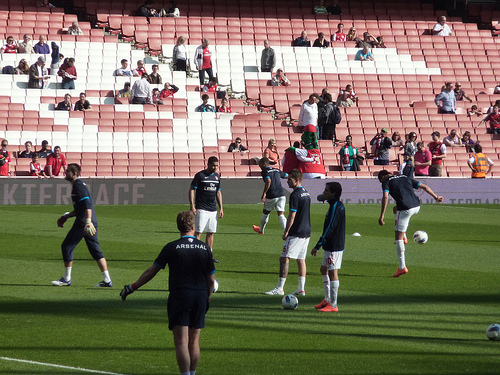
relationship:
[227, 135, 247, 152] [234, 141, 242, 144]
man wearing black sunglasses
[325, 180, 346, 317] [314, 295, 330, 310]
man wearing shoe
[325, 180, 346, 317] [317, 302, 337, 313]
man wearing shoe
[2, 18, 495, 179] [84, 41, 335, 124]
people on bunch seats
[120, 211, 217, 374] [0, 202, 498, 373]
man around field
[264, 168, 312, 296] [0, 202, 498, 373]
man around field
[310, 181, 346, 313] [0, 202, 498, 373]
man around field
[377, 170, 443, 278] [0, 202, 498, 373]
man around field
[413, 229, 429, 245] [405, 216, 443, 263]
ball in air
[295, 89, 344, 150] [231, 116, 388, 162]
people on stands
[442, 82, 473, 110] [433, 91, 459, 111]
person holds mascot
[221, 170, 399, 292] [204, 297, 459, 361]
people on astroturf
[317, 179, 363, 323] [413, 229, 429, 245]
man kick ball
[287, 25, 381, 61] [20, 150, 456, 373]
crowd watch soccer game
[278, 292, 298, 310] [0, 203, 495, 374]
ball on ground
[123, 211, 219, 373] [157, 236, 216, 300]
man wearing t-shirt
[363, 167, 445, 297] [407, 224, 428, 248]
man kicking ball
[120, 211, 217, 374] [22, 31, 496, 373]
man practicing on field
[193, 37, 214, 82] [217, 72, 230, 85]
person looking for seat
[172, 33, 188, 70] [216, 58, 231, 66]
person looking for seat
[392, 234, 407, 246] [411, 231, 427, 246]
foot kicking ball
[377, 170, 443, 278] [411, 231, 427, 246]
man kicking ball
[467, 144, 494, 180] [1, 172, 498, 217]
person standing against wall